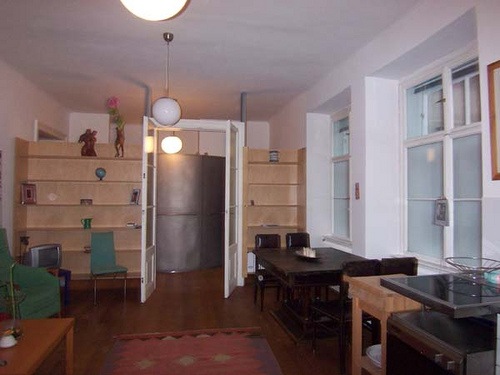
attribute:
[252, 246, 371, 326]
table — wooden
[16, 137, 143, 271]
shelves — in the picture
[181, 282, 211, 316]
flooring — hardwood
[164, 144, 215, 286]
silver — in the picture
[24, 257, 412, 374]
floor — in the picture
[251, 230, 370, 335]
table — dark-colored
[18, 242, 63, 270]
television — small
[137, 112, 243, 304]
doors — white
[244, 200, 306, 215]
shelf — wooden, light brown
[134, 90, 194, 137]
light — in the picture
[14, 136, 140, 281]
shelf — light brown, wooden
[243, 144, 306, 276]
shelf — wooden, light brown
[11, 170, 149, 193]
shelf — light brown, wooden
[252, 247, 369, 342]
table — dark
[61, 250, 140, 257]
shelf — light brown, wooden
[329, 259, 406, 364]
table — small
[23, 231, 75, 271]
television — small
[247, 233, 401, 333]
table — in the picture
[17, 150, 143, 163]
shelf — light brown, wooden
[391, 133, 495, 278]
door — white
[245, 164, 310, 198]
shelf — wooden, light brown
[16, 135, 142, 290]
bookcase — light wood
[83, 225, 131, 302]
chair — blue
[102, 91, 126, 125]
flower — pink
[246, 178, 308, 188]
shelf — light brown, wooden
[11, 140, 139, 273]
shelf — wooden, light brown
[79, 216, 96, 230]
pitcher — small, green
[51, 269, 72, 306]
table — small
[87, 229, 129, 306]
chair — green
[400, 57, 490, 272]
window — in the picture, double wood framed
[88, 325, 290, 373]
rug — red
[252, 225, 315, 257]
chairs — dark-colored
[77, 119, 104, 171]
sculpture — brown